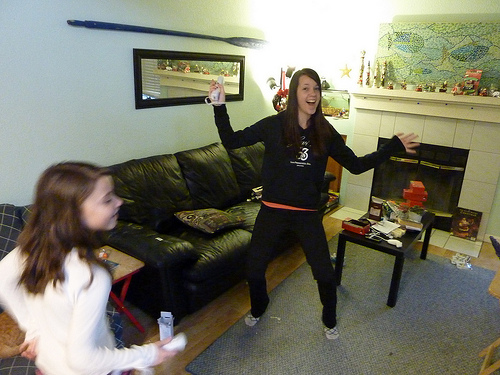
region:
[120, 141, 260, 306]
The couch is covered with black leather.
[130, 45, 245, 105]
Rectangular framed mirror.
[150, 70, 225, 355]
Girls holding wii remote controllers.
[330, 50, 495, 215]
Decorated fireplace.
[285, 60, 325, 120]
The girl is smiling.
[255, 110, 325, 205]
Girl wearing a black sweatshirt.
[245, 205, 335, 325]
The girl is wearing black pants.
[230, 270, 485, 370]
The rug is grey colored.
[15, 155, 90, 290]
The girl has brown hair.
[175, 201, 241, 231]
The cushion has brown and grey small prints.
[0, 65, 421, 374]
two girls playing Wii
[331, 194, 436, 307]
a small black coffee table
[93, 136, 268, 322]
a black leather couch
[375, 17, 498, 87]
picture above the mantle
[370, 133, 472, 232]
an empty fireplace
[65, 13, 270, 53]
blue paddle on wall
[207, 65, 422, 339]
girl all in black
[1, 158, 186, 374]
girl in white shirt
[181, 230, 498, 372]
grey rug on floor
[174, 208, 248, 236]
square pillow on couch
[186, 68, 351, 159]
A woman is holding a remote.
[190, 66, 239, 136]
The color of a remote is white.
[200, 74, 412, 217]
A woman is wearing a black and white top.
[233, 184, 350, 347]
A woman is wearing black pants.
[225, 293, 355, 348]
A woman is wearing white shoes.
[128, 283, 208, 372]
A young girl is holding a remote.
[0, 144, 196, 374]
A young girl is wearing a white top.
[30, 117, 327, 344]
The color of a sofa is black.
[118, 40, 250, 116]
A picture is hanging on a wall.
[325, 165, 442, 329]
A table is behind a woman.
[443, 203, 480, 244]
santa claus book on fire place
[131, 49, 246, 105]
mirror on back wall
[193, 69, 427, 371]
girl standing with wii remote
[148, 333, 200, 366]
wii remote in hand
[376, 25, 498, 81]
mural on back of fireplace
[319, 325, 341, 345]
sock foot of girl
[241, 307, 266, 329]
sock foot of girl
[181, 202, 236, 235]
pillow on black couch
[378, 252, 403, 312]
leg of coffee table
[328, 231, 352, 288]
leg of coffee table table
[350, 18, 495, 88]
green painting hanging above fireplace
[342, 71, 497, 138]
white wooden mantel over fireplace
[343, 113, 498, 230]
white tile around fireplace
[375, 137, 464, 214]
black fireplace screen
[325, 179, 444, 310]
black wooden coffee table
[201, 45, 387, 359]
a woman dressed in black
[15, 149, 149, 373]
a girl in a white shirt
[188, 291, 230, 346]
light brown hard wood floor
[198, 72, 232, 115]
white video game controller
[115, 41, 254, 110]
black framed mirror on wall